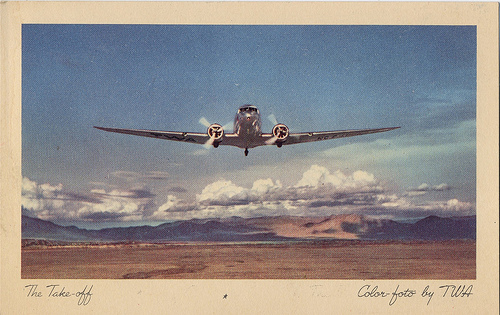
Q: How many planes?
A: One.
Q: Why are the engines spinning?
A: The plane is flying.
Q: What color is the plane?
A: Silver.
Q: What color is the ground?
A: Tan.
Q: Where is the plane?
A: The air.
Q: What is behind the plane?
A: The mountains.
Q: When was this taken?
A: During the day.